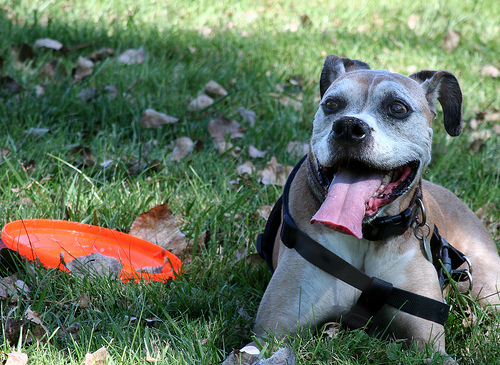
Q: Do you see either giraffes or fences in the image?
A: No, there are no fences or giraffes.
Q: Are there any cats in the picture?
A: No, there are no cats.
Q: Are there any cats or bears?
A: No, there are no cats or bears.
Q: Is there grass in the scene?
A: Yes, there is grass.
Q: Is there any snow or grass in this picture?
A: Yes, there is grass.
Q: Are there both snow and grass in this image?
A: No, there is grass but no snow.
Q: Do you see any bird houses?
A: No, there are no bird houses.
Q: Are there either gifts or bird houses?
A: No, there are no bird houses or gifts.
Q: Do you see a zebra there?
A: No, there are no zebras.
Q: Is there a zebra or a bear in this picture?
A: No, there are no zebras or bears.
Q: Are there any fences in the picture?
A: No, there are no fences.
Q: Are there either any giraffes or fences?
A: No, there are no fences or giraffes.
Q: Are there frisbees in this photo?
A: Yes, there is a frisbee.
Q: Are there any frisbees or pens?
A: Yes, there is a frisbee.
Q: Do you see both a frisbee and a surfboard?
A: No, there is a frisbee but no surfboards.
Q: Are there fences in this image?
A: No, there are no fences.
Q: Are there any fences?
A: No, there are no fences.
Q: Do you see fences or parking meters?
A: No, there are no fences or parking meters.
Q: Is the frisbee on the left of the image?
A: Yes, the frisbee is on the left of the image.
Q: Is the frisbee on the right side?
A: No, the frisbee is on the left of the image.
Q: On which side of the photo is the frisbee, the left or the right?
A: The frisbee is on the left of the image.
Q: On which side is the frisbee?
A: The frisbee is on the left of the image.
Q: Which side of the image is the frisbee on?
A: The frisbee is on the left of the image.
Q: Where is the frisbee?
A: The frisbee is on the grass.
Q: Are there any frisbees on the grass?
A: Yes, there is a frisbee on the grass.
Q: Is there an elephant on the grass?
A: No, there is a frisbee on the grass.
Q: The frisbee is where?
A: The frisbee is in the grass.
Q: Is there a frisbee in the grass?
A: Yes, there is a frisbee in the grass.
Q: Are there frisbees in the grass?
A: Yes, there is a frisbee in the grass.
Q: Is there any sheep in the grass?
A: No, there is a frisbee in the grass.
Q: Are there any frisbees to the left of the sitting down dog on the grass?
A: Yes, there is a frisbee to the left of the dog.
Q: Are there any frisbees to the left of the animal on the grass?
A: Yes, there is a frisbee to the left of the dog.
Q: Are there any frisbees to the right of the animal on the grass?
A: No, the frisbee is to the left of the dog.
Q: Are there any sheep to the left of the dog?
A: No, there is a frisbee to the left of the dog.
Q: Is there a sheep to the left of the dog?
A: No, there is a frisbee to the left of the dog.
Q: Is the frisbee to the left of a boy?
A: No, the frisbee is to the left of the dog.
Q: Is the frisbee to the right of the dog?
A: No, the frisbee is to the left of the dog.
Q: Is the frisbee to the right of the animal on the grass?
A: No, the frisbee is to the left of the dog.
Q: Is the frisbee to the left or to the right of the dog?
A: The frisbee is to the left of the dog.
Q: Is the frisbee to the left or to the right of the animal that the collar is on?
A: The frisbee is to the left of the dog.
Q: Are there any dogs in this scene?
A: Yes, there is a dog.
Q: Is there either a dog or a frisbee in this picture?
A: Yes, there is a dog.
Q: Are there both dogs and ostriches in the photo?
A: No, there is a dog but no ostriches.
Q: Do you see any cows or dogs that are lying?
A: Yes, the dog is lying.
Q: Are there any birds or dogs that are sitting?
A: Yes, the dog is sitting.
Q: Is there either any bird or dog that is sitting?
A: Yes, the dog is sitting.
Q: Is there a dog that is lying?
A: Yes, there is a dog that is lying.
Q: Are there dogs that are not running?
A: Yes, there is a dog that is lying.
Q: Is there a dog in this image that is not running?
A: Yes, there is a dog that is lying.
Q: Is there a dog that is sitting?
A: Yes, there is a dog that is sitting.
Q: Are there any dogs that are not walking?
A: Yes, there is a dog that is sitting.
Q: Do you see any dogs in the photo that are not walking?
A: Yes, there is a dog that is sitting .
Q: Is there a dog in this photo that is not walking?
A: Yes, there is a dog that is sitting.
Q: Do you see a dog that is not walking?
A: Yes, there is a dog that is sitting .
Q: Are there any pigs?
A: No, there are no pigs.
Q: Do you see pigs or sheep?
A: No, there are no pigs or sheep.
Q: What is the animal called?
A: The animal is a dog.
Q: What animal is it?
A: The animal is a dog.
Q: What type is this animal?
A: This is a dog.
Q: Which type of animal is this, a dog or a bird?
A: This is a dog.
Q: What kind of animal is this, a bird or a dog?
A: This is a dog.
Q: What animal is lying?
A: The animal is a dog.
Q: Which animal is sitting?
A: The animal is a dog.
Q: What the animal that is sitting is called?
A: The animal is a dog.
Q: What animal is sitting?
A: The animal is a dog.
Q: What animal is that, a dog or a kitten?
A: That is a dog.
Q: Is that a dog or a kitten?
A: That is a dog.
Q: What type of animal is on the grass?
A: The animal is a dog.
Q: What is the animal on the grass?
A: The animal is a dog.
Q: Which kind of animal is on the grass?
A: The animal is a dog.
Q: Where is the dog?
A: The dog is on the grass.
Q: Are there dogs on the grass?
A: Yes, there is a dog on the grass.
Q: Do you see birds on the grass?
A: No, there is a dog on the grass.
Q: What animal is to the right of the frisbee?
A: The animal is a dog.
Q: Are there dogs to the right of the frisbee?
A: Yes, there is a dog to the right of the frisbee.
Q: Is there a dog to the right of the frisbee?
A: Yes, there is a dog to the right of the frisbee.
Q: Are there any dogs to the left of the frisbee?
A: No, the dog is to the right of the frisbee.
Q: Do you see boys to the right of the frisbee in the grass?
A: No, there is a dog to the right of the frisbee.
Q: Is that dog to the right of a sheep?
A: No, the dog is to the right of the frisbee.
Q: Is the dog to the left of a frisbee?
A: No, the dog is to the right of a frisbee.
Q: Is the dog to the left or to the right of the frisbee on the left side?
A: The dog is to the right of the frisbee.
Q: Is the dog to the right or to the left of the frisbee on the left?
A: The dog is to the right of the frisbee.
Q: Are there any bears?
A: No, there are no bears.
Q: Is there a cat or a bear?
A: No, there are no bears or cats.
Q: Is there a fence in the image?
A: No, there are no fences.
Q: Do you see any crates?
A: No, there are no crates.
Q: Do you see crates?
A: No, there are no crates.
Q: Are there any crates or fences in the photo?
A: No, there are no crates or fences.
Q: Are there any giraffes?
A: No, there are no giraffes.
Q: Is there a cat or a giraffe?
A: No, there are no giraffes or cats.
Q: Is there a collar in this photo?
A: Yes, there is a collar.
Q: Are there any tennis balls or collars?
A: Yes, there is a collar.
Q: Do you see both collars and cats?
A: No, there is a collar but no cats.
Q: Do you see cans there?
A: No, there are no cans.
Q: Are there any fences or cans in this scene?
A: No, there are no cans or fences.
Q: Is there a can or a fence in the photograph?
A: No, there are no cans or fences.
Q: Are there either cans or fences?
A: No, there are no cans or fences.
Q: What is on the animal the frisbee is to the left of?
A: The collar is on the dog.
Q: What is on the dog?
A: The collar is on the dog.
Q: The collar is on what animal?
A: The collar is on the dog.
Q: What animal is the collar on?
A: The collar is on the dog.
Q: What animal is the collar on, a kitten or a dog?
A: The collar is on a dog.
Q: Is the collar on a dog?
A: Yes, the collar is on a dog.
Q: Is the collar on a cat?
A: No, the collar is on a dog.